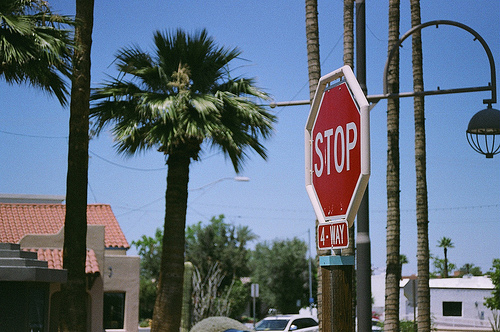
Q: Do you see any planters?
A: No, there are no planters.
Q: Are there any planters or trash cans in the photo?
A: No, there are no planters or trash cans.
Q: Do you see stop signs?
A: Yes, there is a stop sign.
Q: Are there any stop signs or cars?
A: Yes, there is a stop sign.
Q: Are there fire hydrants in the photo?
A: No, there are no fire hydrants.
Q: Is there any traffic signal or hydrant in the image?
A: No, there are no fire hydrants or traffic lights.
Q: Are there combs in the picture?
A: No, there are no combs.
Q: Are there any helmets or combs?
A: No, there are no combs or helmets.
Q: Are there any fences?
A: No, there are no fences.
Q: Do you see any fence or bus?
A: No, there are no fences or buses.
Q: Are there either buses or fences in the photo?
A: No, there are no fences or buses.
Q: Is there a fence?
A: No, there are no fences.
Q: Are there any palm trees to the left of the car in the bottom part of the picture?
A: Yes, there is a palm tree to the left of the car.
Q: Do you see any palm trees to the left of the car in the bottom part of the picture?
A: Yes, there is a palm tree to the left of the car.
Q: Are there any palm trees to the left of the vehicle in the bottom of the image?
A: Yes, there is a palm tree to the left of the car.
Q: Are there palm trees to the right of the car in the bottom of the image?
A: No, the palm tree is to the left of the car.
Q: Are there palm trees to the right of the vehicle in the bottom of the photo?
A: No, the palm tree is to the left of the car.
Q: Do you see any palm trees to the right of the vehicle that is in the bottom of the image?
A: No, the palm tree is to the left of the car.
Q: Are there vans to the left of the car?
A: No, there is a palm tree to the left of the car.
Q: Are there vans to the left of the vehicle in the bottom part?
A: No, there is a palm tree to the left of the car.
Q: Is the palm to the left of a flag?
A: No, the palm is to the left of a car.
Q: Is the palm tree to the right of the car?
A: No, the palm tree is to the left of the car.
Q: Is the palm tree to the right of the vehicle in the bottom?
A: No, the palm tree is to the left of the car.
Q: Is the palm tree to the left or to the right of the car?
A: The palm tree is to the left of the car.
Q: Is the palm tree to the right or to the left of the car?
A: The palm tree is to the left of the car.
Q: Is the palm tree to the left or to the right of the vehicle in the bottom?
A: The palm tree is to the left of the car.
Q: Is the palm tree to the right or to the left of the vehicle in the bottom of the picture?
A: The palm tree is to the left of the car.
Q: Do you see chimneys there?
A: No, there are no chimneys.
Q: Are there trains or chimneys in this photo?
A: No, there are no chimneys or trains.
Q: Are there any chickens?
A: No, there are no chickens.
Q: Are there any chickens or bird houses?
A: No, there are no chickens or bird houses.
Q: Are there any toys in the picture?
A: No, there are no toys.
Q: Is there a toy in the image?
A: No, there are no toys.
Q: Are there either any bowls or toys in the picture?
A: No, there are no toys or bowls.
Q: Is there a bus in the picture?
A: No, there are no buses.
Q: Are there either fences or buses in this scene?
A: No, there are no buses or fences.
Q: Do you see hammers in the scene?
A: No, there are no hammers.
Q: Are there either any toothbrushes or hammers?
A: No, there are no hammers or toothbrushes.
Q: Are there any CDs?
A: No, there are no cds.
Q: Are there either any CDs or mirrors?
A: No, there are no CDs or mirrors.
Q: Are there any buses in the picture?
A: No, there are no buses.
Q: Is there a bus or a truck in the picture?
A: No, there are no buses or trucks.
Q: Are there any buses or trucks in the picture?
A: No, there are no buses or trucks.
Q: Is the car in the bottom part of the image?
A: Yes, the car is in the bottom of the image.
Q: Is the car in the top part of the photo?
A: No, the car is in the bottom of the image.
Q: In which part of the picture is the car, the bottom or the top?
A: The car is in the bottom of the image.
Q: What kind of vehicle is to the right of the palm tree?
A: The vehicle is a car.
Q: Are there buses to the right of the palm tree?
A: No, there is a car to the right of the palm tree.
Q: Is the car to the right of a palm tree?
A: Yes, the car is to the right of a palm tree.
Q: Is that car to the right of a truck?
A: No, the car is to the right of a palm tree.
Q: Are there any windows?
A: Yes, there is a window.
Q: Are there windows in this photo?
A: Yes, there is a window.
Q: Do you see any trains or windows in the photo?
A: Yes, there is a window.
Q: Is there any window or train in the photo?
A: Yes, there is a window.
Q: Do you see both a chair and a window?
A: No, there is a window but no chairs.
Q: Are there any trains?
A: No, there are no trains.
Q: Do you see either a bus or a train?
A: No, there are no trains or buses.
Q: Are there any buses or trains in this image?
A: No, there are no trains or buses.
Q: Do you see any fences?
A: No, there are no fences.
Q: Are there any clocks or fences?
A: No, there are no fences or clocks.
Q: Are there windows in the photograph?
A: Yes, there is a window.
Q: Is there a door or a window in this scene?
A: Yes, there is a window.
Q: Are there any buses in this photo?
A: No, there are no buses.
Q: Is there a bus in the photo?
A: No, there are no buses.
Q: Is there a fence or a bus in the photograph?
A: No, there are no fences or buses.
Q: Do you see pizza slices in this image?
A: No, there are no pizza slices.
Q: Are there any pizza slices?
A: No, there are no pizza slices.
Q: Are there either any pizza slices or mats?
A: No, there are no pizza slices or mats.